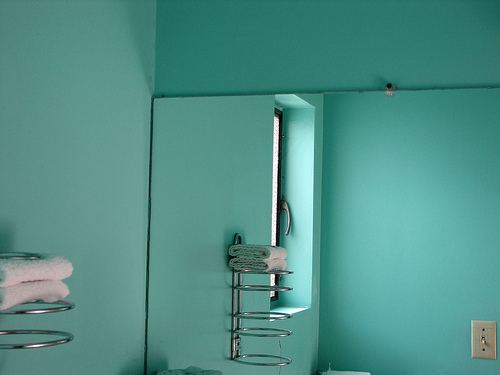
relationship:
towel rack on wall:
[0, 252, 75, 350] [0, 0, 155, 375]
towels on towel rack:
[0, 256, 74, 311] [0, 252, 75, 350]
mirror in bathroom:
[145, 86, 498, 374] [0, 0, 499, 374]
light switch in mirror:
[470, 320, 496, 361] [145, 86, 498, 374]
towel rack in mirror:
[0, 252, 75, 350] [145, 86, 498, 374]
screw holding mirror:
[386, 83, 394, 93] [145, 86, 498, 374]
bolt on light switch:
[482, 328, 486, 331] [470, 320, 496, 361]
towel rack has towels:
[0, 252, 75, 350] [0, 256, 74, 311]